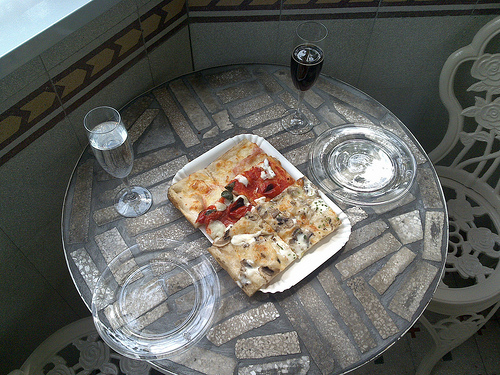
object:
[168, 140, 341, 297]
pizza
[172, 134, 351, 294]
plate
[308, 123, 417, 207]
plate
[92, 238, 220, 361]
plate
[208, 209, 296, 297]
pizza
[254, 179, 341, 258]
pizza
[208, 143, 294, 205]
pizza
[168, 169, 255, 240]
pizza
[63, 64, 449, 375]
table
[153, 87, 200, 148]
inlaid stone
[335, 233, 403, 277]
inlaid stone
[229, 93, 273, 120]
inlaid stone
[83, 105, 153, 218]
glass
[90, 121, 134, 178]
water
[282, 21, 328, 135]
glass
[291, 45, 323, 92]
soda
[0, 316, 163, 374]
chair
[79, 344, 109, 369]
flower design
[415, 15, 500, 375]
chair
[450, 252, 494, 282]
flower design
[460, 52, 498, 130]
flower design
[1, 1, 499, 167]
border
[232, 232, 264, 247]
mushroom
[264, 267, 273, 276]
mushroom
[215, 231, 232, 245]
mushroom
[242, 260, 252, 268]
mushroom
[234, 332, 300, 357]
inlaid stone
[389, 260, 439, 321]
inlaid stone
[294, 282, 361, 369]
inlaid stone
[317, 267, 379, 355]
inlaid stone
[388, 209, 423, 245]
inlaid stone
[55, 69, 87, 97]
yellow arrow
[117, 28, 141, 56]
yellow arrow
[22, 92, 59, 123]
yellow arrow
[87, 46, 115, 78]
yellow arrow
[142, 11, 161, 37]
yellow arrow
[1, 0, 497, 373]
wall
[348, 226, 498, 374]
ground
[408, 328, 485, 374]
brick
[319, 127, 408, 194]
reflection